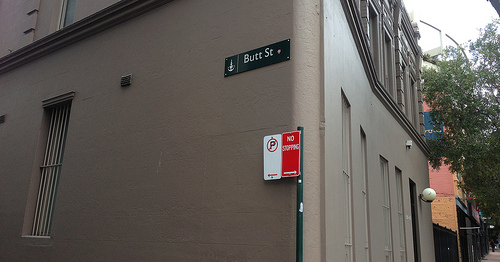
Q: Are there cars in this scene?
A: No, there are no cars.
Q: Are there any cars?
A: No, there are no cars.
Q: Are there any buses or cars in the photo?
A: No, there are no cars or buses.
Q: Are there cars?
A: No, there are no cars.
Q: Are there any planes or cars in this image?
A: No, there are no cars or planes.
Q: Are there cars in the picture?
A: No, there are no cars.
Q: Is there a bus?
A: No, there are no buses.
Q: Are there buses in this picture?
A: No, there are no buses.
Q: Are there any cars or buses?
A: No, there are no buses or cars.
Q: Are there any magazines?
A: No, there are no magazines.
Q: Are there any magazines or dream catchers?
A: No, there are no magazines or dream catchers.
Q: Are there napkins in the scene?
A: No, there are no napkins.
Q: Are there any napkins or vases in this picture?
A: No, there are no napkins or vases.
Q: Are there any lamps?
A: Yes, there is a lamp.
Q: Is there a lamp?
A: Yes, there is a lamp.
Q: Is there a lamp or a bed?
A: Yes, there is a lamp.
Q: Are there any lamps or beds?
A: Yes, there is a lamp.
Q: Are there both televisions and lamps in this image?
A: No, there is a lamp but no televisions.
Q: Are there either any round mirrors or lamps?
A: Yes, there is a round lamp.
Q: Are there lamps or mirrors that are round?
A: Yes, the lamp is round.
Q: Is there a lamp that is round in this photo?
A: Yes, there is a round lamp.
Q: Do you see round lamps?
A: Yes, there is a round lamp.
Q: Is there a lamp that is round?
A: Yes, there is a lamp that is round.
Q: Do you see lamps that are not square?
A: Yes, there is a round lamp.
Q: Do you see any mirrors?
A: No, there are no mirrors.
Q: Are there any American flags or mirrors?
A: No, there are no mirrors or American flags.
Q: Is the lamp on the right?
A: Yes, the lamp is on the right of the image.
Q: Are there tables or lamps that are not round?
A: No, there is a lamp but it is round.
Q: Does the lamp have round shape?
A: Yes, the lamp is round.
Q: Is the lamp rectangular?
A: No, the lamp is round.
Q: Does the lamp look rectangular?
A: No, the lamp is round.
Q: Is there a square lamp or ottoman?
A: No, there is a lamp but it is round.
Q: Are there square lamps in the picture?
A: No, there is a lamp but it is round.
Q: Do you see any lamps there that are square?
A: No, there is a lamp but it is round.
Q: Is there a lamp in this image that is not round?
A: No, there is a lamp but it is round.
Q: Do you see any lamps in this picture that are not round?
A: No, there is a lamp but it is round.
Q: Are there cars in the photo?
A: No, there are no cars.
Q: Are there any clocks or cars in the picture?
A: No, there are no cars or clocks.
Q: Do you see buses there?
A: No, there are no buses.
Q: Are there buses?
A: No, there are no buses.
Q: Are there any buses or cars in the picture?
A: No, there are no buses or cars.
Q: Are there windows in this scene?
A: Yes, there are windows.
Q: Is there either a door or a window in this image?
A: Yes, there are windows.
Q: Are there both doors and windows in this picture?
A: Yes, there are both windows and doors.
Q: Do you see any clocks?
A: No, there are no clocks.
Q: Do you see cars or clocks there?
A: No, there are no clocks or cars.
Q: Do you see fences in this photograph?
A: Yes, there is a fence.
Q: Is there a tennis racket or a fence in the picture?
A: Yes, there is a fence.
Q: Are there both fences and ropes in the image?
A: No, there is a fence but no ropes.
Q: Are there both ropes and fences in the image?
A: No, there is a fence but no ropes.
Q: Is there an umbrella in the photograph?
A: No, there are no umbrellas.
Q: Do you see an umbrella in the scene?
A: No, there are no umbrellas.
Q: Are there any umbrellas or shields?
A: No, there are no umbrellas or shields.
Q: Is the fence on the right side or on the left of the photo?
A: The fence is on the right of the image.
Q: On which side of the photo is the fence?
A: The fence is on the right of the image.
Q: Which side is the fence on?
A: The fence is on the right of the image.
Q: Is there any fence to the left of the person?
A: Yes, there is a fence to the left of the person.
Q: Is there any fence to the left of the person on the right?
A: Yes, there is a fence to the left of the person.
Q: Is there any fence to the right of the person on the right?
A: No, the fence is to the left of the person.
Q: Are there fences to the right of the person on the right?
A: No, the fence is to the left of the person.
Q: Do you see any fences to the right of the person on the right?
A: No, the fence is to the left of the person.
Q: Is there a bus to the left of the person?
A: No, there is a fence to the left of the person.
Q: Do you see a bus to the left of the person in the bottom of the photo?
A: No, there is a fence to the left of the person.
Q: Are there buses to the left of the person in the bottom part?
A: No, there is a fence to the left of the person.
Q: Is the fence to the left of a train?
A: No, the fence is to the left of a person.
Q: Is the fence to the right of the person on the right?
A: No, the fence is to the left of the person.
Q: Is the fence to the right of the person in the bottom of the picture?
A: No, the fence is to the left of the person.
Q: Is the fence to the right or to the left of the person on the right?
A: The fence is to the left of the person.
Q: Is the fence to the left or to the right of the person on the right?
A: The fence is to the left of the person.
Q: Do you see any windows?
A: Yes, there is a window.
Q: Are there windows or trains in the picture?
A: Yes, there is a window.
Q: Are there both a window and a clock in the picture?
A: No, there is a window but no clocks.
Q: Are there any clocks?
A: No, there are no clocks.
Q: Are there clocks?
A: No, there are no clocks.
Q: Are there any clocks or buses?
A: No, there are no clocks or buses.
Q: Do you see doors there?
A: Yes, there is a door.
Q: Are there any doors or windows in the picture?
A: Yes, there is a door.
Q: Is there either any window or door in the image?
A: Yes, there is a door.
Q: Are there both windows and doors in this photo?
A: Yes, there are both a door and a window.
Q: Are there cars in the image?
A: No, there are no cars.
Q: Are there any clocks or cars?
A: No, there are no cars or clocks.